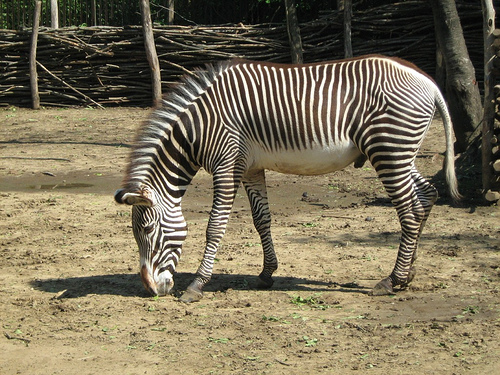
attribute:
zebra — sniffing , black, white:
[112, 53, 456, 300]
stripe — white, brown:
[363, 144, 418, 159]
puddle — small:
[21, 177, 102, 194]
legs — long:
[164, 156, 449, 267]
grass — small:
[287, 290, 351, 321]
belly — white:
[258, 152, 343, 174]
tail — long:
[435, 87, 470, 207]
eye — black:
[95, 196, 156, 248]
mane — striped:
[136, 99, 173, 144]